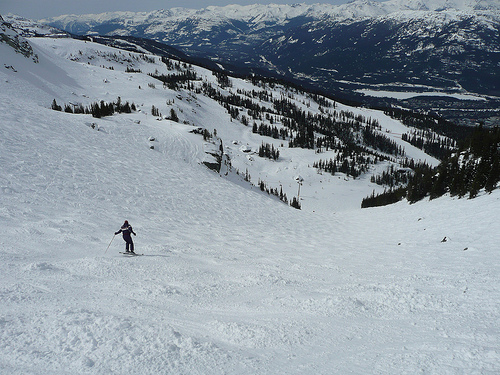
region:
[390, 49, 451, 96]
white clouds in blue sky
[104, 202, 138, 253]
skier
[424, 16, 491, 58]
white clouds in blue sky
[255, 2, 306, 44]
white clouds in blue sky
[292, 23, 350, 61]
white clouds in blue sky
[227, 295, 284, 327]
white snow on hill side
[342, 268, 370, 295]
white snow on hill side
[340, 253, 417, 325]
white snow on hill side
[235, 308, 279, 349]
white snow on hill side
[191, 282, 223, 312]
white snow on hill sidewhite snow on hill side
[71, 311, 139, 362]
white snow on hill side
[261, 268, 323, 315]
white snow on hill side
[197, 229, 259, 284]
white snow on hill side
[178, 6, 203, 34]
white clouds in blue sky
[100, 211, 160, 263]
skier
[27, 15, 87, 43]
white clouds in blue sky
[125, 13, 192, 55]
white clouds in blue sky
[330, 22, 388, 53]
white clouds in blue sky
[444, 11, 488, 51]
white clouds in blue sky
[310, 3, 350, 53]
white clouds in blue sky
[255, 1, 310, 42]
white clouds in blue sky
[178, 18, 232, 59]
white clouds in blue sky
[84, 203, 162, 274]
skier in white snow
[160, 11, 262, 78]
white snow on hill side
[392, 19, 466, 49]
white snow on hill side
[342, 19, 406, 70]
white snow on hill side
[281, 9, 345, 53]
white snow on hill side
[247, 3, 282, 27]
white snow on hill side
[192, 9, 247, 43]
white snow on hill side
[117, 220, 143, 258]
a person is skiing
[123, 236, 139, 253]
the pants are black